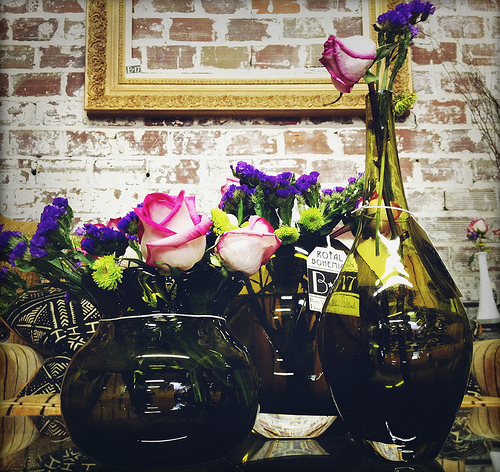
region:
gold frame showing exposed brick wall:
[33, 2, 433, 118]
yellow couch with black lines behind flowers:
[0, 296, 491, 456]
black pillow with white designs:
[5, 290, 95, 395]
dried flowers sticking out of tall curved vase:
[315, 2, 425, 102]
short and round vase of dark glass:
[10, 260, 275, 460]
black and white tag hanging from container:
[307, 225, 358, 320]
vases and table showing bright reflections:
[242, 405, 402, 460]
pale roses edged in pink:
[132, 186, 277, 271]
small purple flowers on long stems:
[30, 191, 75, 256]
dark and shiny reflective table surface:
[2, 415, 432, 466]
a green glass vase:
[291, 82, 483, 464]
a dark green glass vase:
[48, 259, 304, 468]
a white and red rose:
[123, 182, 218, 288]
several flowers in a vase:
[3, 163, 301, 469]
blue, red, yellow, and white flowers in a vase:
[3, 140, 335, 315]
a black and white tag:
[306, 239, 366, 332]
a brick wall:
[13, 120, 359, 187]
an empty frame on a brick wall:
[53, 2, 470, 151]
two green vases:
[26, 98, 493, 468]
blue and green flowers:
[206, 155, 335, 204]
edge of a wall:
[321, 153, 334, 173]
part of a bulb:
[164, 383, 184, 403]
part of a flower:
[228, 246, 240, 266]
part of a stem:
[136, 279, 150, 291]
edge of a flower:
[173, 284, 191, 326]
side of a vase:
[405, 345, 426, 369]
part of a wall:
[451, 230, 460, 265]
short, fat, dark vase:
[47, 267, 282, 465]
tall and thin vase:
[322, 92, 482, 469]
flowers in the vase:
[4, 186, 306, 465]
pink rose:
[124, 183, 211, 278]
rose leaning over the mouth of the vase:
[311, 2, 449, 236]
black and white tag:
[303, 236, 367, 321]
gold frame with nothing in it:
[68, 1, 440, 124]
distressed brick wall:
[3, 4, 498, 309]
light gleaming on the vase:
[372, 233, 418, 299]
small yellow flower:
[87, 253, 127, 291]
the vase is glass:
[45, 313, 280, 460]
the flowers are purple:
[22, 200, 124, 257]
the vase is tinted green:
[323, 179, 456, 461]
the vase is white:
[467, 247, 497, 323]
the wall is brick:
[417, 127, 477, 206]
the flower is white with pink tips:
[127, 187, 213, 272]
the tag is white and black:
[297, 242, 329, 313]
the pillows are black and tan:
[26, 302, 68, 354]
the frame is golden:
[132, 67, 314, 132]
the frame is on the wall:
[82, 40, 302, 142]